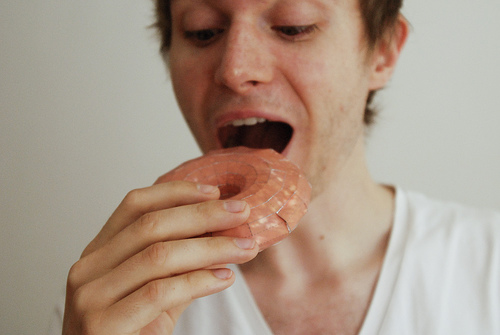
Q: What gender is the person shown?
A: Male.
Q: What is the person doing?
A: Eating.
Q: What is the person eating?
A: Doughnut.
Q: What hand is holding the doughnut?
A: Right.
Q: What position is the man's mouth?
A: Open.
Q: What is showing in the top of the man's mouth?
A: Teeth.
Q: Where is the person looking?
A: At the doughnut.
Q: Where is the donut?
A: In the hand.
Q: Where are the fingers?
A: On the hand.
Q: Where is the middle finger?
A: On the man.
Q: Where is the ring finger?
A: On the hand.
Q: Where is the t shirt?
A: On the man.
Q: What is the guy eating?
A: A donut.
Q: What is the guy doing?
A: Eating.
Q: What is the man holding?
A: A donut.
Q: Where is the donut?
A: In the man's hand.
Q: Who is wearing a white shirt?
A: The man.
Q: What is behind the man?
A: A wall.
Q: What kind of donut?
A: Glazed.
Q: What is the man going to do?
A: Eat the donut.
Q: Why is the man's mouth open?
A: Going to take a bite.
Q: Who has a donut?
A: The man.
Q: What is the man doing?
A: Eating a donut.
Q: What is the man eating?
A: A donut.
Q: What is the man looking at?
A: A donut.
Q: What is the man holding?
A: A donut.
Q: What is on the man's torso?
A: A white v-neck shirt.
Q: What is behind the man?
A: A white wall.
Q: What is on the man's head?
A: Hair.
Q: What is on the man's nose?
A: Freckles.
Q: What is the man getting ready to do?
A: Eat a donut.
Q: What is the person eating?
A: Donut.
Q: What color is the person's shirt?
A: White.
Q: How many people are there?
A: 1.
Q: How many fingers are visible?
A: 4.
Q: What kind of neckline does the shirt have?
A: V-neck.